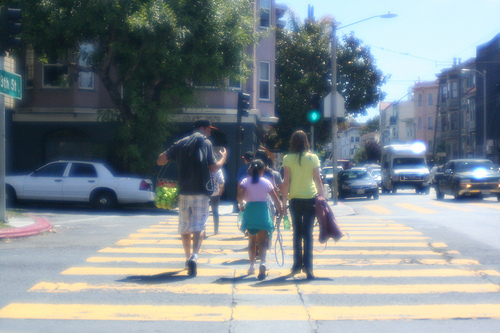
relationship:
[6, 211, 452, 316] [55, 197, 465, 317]
lines on street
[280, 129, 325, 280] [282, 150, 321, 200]
adult wearing a shirt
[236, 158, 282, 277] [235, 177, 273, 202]
child wearing a shirt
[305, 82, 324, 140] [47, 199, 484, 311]
light on intersection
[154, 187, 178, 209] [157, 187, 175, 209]
balls of balls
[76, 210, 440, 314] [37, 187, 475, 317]
crossing area on street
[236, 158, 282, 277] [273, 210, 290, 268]
child carrying tennis racket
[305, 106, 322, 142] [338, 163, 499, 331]
traffic light by street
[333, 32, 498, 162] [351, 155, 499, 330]
buildings along street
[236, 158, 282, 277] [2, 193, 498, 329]
child crossing street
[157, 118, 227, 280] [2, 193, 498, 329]
adult crossing street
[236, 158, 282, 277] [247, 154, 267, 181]
child has head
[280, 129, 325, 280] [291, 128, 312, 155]
adult has head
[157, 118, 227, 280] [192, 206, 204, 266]
adult has leg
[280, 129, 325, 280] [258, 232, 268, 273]
adult has leg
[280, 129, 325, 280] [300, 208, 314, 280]
adult has leg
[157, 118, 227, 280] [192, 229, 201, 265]
adult has leg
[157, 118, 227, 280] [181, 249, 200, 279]
adult has feet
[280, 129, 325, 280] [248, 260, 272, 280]
adult has feet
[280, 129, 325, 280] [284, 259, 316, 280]
adult has feet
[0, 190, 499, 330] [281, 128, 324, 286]
pedestrian walking on street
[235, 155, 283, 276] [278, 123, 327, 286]
child walking with adult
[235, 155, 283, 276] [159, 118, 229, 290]
child walking with adult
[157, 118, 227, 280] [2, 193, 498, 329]
adult walking on street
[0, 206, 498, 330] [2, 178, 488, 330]
crosswalk on street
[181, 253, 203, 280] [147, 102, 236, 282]
foot of pedestrian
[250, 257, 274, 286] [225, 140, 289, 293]
foot of child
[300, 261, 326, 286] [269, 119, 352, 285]
foot of person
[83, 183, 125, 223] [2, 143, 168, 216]
wheel of car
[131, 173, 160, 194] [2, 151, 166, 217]
light of car